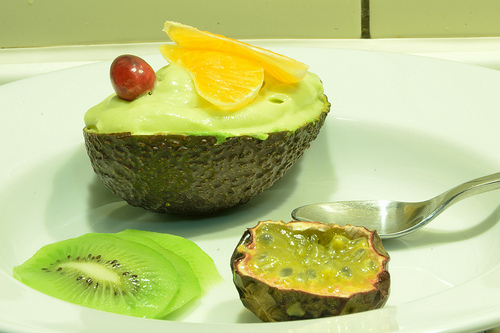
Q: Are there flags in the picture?
A: No, there are no flags.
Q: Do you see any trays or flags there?
A: No, there are no flags or trays.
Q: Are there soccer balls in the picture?
A: No, there are no soccer balls.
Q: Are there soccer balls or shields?
A: No, there are no soccer balls or shields.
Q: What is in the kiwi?
A: The seeds are in the kiwi.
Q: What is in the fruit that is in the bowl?
A: The seeds are in the kiwi.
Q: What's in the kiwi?
A: The seeds are in the kiwi.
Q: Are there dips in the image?
A: No, there are no dips.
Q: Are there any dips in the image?
A: No, there are no dips.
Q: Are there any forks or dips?
A: No, there are no dips or forks.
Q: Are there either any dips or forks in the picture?
A: No, there are no dips or forks.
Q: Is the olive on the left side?
A: Yes, the olive is on the left of the image.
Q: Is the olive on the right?
A: No, the olive is on the left of the image.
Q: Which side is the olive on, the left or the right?
A: The olive is on the left of the image.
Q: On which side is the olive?
A: The olive is on the left of the image.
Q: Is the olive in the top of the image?
A: Yes, the olive is in the top of the image.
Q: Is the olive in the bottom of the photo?
A: No, the olive is in the top of the image.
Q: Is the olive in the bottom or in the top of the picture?
A: The olive is in the top of the image.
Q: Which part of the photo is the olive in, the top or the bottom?
A: The olive is in the top of the image.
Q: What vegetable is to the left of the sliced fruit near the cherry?
A: The vegetable is an olive.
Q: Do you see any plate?
A: Yes, there is a plate.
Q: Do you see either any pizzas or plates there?
A: Yes, there is a plate.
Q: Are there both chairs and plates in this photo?
A: No, there is a plate but no chairs.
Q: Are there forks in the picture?
A: No, there are no forks.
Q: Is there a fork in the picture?
A: No, there are no forks.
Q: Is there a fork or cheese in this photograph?
A: No, there are no forks or cheese.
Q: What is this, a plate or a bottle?
A: This is a plate.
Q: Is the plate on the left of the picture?
A: No, the plate is on the right of the image.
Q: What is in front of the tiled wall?
A: The plate is in front of the wall.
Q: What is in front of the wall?
A: The plate is in front of the wall.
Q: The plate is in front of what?
A: The plate is in front of the wall.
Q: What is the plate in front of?
A: The plate is in front of the wall.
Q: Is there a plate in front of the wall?
A: Yes, there is a plate in front of the wall.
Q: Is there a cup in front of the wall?
A: No, there is a plate in front of the wall.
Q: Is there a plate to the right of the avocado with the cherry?
A: Yes, there is a plate to the right of the avocado.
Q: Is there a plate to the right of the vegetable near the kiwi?
A: Yes, there is a plate to the right of the avocado.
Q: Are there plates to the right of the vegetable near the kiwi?
A: Yes, there is a plate to the right of the avocado.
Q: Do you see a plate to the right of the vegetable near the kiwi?
A: Yes, there is a plate to the right of the avocado.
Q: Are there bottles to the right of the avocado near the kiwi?
A: No, there is a plate to the right of the avocado.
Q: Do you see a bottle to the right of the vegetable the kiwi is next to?
A: No, there is a plate to the right of the avocado.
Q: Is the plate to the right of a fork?
A: No, the plate is to the right of the avocado.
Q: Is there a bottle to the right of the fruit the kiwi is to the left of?
A: No, there is a plate to the right of the fruit.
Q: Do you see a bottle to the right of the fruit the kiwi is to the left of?
A: No, there is a plate to the right of the fruit.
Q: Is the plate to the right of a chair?
A: No, the plate is to the right of the fruit.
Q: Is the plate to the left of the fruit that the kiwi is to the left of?
A: No, the plate is to the right of the fruit.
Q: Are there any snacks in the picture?
A: No, there are no snacks.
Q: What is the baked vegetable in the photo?
A: The vegetable is an avocado.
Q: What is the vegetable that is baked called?
A: The vegetable is an avocado.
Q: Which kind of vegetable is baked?
A: The vegetable is an avocado.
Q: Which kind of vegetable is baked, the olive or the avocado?
A: The avocado is baked.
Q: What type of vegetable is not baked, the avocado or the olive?
A: The olive is not baked.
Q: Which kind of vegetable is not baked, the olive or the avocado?
A: The olive is not baked.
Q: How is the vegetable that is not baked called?
A: The vegetable is an olive.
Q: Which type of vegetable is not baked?
A: The vegetable is an olive.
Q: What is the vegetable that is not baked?
A: The vegetable is an olive.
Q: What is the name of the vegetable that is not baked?
A: The vegetable is an olive.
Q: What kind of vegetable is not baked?
A: The vegetable is an olive.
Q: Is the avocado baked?
A: Yes, the avocado is baked.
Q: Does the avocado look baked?
A: Yes, the avocado is baked.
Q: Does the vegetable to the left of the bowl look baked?
A: Yes, the avocado is baked.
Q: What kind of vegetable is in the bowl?
A: The vegetable is an avocado.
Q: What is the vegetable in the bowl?
A: The vegetable is an avocado.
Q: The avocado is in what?
A: The avocado is in the bowl.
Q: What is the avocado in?
A: The avocado is in the bowl.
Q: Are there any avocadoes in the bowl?
A: Yes, there is an avocado in the bowl.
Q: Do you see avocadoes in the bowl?
A: Yes, there is an avocado in the bowl.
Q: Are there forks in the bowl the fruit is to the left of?
A: No, there is an avocado in the bowl.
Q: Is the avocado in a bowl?
A: Yes, the avocado is in a bowl.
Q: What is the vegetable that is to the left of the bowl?
A: The vegetable is an avocado.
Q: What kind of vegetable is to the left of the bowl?
A: The vegetable is an avocado.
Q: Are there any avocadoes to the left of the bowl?
A: Yes, there is an avocado to the left of the bowl.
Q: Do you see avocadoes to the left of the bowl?
A: Yes, there is an avocado to the left of the bowl.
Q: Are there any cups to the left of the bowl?
A: No, there is an avocado to the left of the bowl.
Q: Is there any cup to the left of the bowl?
A: No, there is an avocado to the left of the bowl.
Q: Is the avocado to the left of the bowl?
A: Yes, the avocado is to the left of the bowl.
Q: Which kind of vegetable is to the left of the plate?
A: The vegetable is an avocado.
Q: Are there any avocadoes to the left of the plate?
A: Yes, there is an avocado to the left of the plate.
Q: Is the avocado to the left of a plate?
A: Yes, the avocado is to the left of a plate.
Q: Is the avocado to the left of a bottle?
A: No, the avocado is to the left of a plate.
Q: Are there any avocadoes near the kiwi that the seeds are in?
A: Yes, there is an avocado near the kiwi.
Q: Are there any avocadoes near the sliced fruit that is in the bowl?
A: Yes, there is an avocado near the kiwi.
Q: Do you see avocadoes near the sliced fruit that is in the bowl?
A: Yes, there is an avocado near the kiwi.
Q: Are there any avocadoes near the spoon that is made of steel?
A: Yes, there is an avocado near the spoon.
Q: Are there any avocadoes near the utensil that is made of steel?
A: Yes, there is an avocado near the spoon.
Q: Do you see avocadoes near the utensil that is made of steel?
A: Yes, there is an avocado near the spoon.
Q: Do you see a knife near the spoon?
A: No, there is an avocado near the spoon.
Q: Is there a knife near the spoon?
A: No, there is an avocado near the spoon.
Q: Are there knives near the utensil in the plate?
A: No, there is an avocado near the spoon.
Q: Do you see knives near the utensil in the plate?
A: No, there is an avocado near the spoon.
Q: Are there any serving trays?
A: No, there are no serving trays.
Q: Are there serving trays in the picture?
A: No, there are no serving trays.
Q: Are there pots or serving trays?
A: No, there are no serving trays or pots.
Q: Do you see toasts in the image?
A: No, there are no toasts.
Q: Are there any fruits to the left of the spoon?
A: Yes, there are fruits to the left of the spoon.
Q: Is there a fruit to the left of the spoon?
A: Yes, there are fruits to the left of the spoon.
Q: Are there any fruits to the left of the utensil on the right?
A: Yes, there are fruits to the left of the spoon.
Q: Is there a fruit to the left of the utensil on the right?
A: Yes, there are fruits to the left of the spoon.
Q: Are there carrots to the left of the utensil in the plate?
A: No, there are fruits to the left of the spoon.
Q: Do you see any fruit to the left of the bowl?
A: Yes, there are fruits to the left of the bowl.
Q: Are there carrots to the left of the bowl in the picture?
A: No, there are fruits to the left of the bowl.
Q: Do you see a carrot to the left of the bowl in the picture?
A: No, there are fruits to the left of the bowl.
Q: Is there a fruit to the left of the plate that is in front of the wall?
A: Yes, there are fruits to the left of the plate.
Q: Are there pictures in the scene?
A: No, there are no pictures.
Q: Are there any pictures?
A: No, there are no pictures.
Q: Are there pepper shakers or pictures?
A: No, there are no pictures or pepper shakers.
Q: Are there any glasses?
A: No, there are no glasses.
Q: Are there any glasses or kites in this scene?
A: No, there are no glasses or kites.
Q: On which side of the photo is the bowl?
A: The bowl is on the right of the image.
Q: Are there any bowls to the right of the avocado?
A: Yes, there is a bowl to the right of the avocado.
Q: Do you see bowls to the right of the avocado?
A: Yes, there is a bowl to the right of the avocado.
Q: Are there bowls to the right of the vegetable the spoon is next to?
A: Yes, there is a bowl to the right of the avocado.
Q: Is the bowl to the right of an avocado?
A: Yes, the bowl is to the right of an avocado.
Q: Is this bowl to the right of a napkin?
A: No, the bowl is to the right of an avocado.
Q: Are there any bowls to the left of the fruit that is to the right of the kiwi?
A: No, the bowl is to the right of the fruit.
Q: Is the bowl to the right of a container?
A: No, the bowl is to the right of a fruit.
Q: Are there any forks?
A: No, there are no forks.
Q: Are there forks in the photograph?
A: No, there are no forks.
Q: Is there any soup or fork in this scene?
A: No, there are no forks or soup.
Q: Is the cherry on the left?
A: Yes, the cherry is on the left of the image.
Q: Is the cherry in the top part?
A: Yes, the cherry is in the top of the image.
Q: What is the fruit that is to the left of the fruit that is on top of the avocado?
A: The fruit is a cherry.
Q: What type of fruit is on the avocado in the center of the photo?
A: The fruit is a cherry.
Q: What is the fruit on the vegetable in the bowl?
A: The fruit is a cherry.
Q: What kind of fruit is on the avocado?
A: The fruit is a cherry.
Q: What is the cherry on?
A: The cherry is on the avocado.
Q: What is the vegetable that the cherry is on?
A: The vegetable is an avocado.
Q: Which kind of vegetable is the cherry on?
A: The cherry is on the avocado.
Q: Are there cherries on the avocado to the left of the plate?
A: Yes, there is a cherry on the avocado.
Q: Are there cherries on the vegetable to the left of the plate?
A: Yes, there is a cherry on the avocado.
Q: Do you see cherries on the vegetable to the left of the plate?
A: Yes, there is a cherry on the avocado.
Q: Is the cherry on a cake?
A: No, the cherry is on the avocado.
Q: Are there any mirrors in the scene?
A: No, there are no mirrors.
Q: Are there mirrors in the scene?
A: No, there are no mirrors.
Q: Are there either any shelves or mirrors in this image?
A: No, there are no mirrors or shelves.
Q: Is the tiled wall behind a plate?
A: Yes, the wall is behind a plate.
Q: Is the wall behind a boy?
A: No, the wall is behind a plate.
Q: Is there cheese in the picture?
A: No, there is no cheese.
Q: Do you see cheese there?
A: No, there is no cheese.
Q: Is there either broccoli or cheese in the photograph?
A: No, there are no cheese or broccoli.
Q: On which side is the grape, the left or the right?
A: The grape is on the left of the image.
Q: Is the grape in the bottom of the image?
A: No, the grape is in the top of the image.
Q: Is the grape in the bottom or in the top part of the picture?
A: The grape is in the top of the image.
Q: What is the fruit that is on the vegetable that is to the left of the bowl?
A: The fruit is a grape.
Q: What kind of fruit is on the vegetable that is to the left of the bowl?
A: The fruit is a grape.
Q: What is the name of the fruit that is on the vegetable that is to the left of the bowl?
A: The fruit is a grape.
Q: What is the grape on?
A: The grape is on the avocado.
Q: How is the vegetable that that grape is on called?
A: The vegetable is an avocado.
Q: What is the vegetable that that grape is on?
A: The vegetable is an avocado.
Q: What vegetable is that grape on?
A: The grape is on the avocado.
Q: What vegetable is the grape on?
A: The grape is on the avocado.